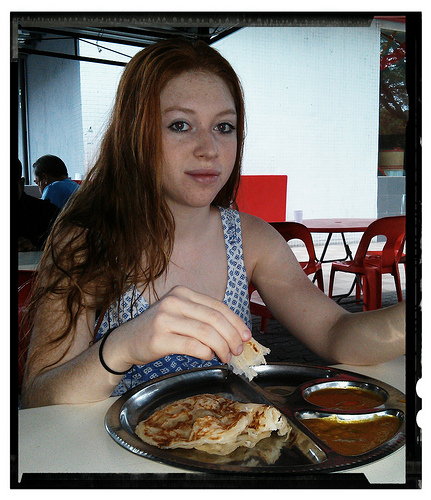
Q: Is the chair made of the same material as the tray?
A: No, the chair is made of plastic and the tray is made of metal.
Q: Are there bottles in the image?
A: No, there are no bottles.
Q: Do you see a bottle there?
A: No, there are no bottles.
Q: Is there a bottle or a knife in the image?
A: No, there are no bottles or knives.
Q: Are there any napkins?
A: No, there are no napkins.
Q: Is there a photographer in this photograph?
A: No, there are no photographers.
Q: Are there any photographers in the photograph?
A: No, there are no photographers.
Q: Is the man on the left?
A: Yes, the man is on the left of the image.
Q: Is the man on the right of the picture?
A: No, the man is on the left of the image.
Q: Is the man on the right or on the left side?
A: The man is on the left of the image.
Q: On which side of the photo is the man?
A: The man is on the left of the image.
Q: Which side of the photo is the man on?
A: The man is on the left of the image.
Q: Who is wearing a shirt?
A: The man is wearing a shirt.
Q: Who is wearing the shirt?
A: The man is wearing a shirt.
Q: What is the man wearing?
A: The man is wearing a shirt.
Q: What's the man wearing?
A: The man is wearing a shirt.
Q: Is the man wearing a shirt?
A: Yes, the man is wearing a shirt.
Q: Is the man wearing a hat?
A: No, the man is wearing a shirt.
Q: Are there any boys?
A: No, there are no boys.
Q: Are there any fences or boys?
A: No, there are no boys or fences.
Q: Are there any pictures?
A: No, there are no pictures.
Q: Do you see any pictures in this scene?
A: No, there are no pictures.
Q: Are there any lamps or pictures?
A: No, there are no pictures or lamps.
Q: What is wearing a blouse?
A: The wall is wearing a blouse.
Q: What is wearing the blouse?
A: The wall is wearing a blouse.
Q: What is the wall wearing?
A: The wall is wearing a blouse.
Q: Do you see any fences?
A: No, there are no fences.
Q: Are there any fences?
A: No, there are no fences.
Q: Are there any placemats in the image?
A: No, there are no placemats.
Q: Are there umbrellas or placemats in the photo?
A: No, there are no placemats or umbrellas.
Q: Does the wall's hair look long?
A: Yes, the hair is long.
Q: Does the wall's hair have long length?
A: Yes, the hair is long.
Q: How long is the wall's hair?
A: The hair is long.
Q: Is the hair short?
A: No, the hair is long.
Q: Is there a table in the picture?
A: Yes, there is a table.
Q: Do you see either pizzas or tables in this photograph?
A: Yes, there is a table.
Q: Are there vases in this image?
A: No, there are no vases.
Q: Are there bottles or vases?
A: No, there are no vases or bottles.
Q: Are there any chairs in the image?
A: Yes, there is a chair.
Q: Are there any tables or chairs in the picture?
A: Yes, there is a chair.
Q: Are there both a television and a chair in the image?
A: No, there is a chair but no televisions.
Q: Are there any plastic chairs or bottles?
A: Yes, there is a plastic chair.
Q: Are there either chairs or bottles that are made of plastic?
A: Yes, the chair is made of plastic.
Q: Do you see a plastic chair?
A: Yes, there is a chair that is made of plastic.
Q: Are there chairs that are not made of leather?
A: Yes, there is a chair that is made of plastic.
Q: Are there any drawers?
A: No, there are no drawers.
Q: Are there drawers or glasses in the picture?
A: No, there are no drawers or glasses.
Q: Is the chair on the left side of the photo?
A: No, the chair is on the right of the image.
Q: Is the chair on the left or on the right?
A: The chair is on the right of the image.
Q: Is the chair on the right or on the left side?
A: The chair is on the right of the image.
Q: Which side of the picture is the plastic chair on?
A: The chair is on the right of the image.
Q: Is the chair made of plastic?
A: Yes, the chair is made of plastic.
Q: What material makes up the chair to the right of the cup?
A: The chair is made of plastic.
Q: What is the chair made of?
A: The chair is made of plastic.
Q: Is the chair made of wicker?
A: No, the chair is made of plastic.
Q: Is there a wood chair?
A: No, there is a chair but it is made of plastic.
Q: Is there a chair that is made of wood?
A: No, there is a chair but it is made of plastic.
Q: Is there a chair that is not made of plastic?
A: No, there is a chair but it is made of plastic.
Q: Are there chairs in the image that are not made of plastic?
A: No, there is a chair but it is made of plastic.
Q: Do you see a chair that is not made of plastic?
A: No, there is a chair but it is made of plastic.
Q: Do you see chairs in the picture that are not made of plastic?
A: No, there is a chair but it is made of plastic.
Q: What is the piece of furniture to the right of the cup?
A: The piece of furniture is a chair.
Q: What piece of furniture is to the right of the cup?
A: The piece of furniture is a chair.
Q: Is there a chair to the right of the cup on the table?
A: Yes, there is a chair to the right of the cup.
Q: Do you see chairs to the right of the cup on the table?
A: Yes, there is a chair to the right of the cup.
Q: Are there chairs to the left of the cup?
A: No, the chair is to the right of the cup.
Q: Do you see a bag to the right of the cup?
A: No, there is a chair to the right of the cup.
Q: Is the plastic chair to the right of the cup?
A: Yes, the chair is to the right of the cup.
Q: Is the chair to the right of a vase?
A: No, the chair is to the right of the cup.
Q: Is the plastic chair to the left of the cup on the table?
A: No, the chair is to the right of the cup.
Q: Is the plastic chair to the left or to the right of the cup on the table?
A: The chair is to the right of the cup.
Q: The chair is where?
A: The chair is at the table.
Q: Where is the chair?
A: The chair is at the table.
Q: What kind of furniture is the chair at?
A: The chair is at the table.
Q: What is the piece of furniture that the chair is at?
A: The piece of furniture is a table.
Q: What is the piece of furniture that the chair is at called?
A: The piece of furniture is a table.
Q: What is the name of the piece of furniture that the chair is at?
A: The piece of furniture is a table.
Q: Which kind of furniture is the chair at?
A: The chair is at the table.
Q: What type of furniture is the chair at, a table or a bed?
A: The chair is at a table.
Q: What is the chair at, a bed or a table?
A: The chair is at a table.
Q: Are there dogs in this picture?
A: No, there are no dogs.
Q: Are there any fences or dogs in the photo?
A: No, there are no dogs or fences.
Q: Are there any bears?
A: No, there are no bears.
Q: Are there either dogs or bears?
A: No, there are no bears or dogs.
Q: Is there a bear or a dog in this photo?
A: No, there are no bears or dogs.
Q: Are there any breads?
A: Yes, there is a bread.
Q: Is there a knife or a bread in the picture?
A: Yes, there is a bread.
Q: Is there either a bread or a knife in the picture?
A: Yes, there is a bread.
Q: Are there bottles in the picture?
A: No, there are no bottles.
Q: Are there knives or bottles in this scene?
A: No, there are no bottles or knives.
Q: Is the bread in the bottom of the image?
A: Yes, the bread is in the bottom of the image.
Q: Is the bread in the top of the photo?
A: No, the bread is in the bottom of the image.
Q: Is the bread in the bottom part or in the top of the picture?
A: The bread is in the bottom of the image.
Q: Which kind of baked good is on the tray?
A: The food is a bread.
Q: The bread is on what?
A: The bread is on the tray.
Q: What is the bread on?
A: The bread is on the tray.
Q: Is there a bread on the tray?
A: Yes, there is a bread on the tray.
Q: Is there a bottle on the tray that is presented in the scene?
A: No, there is a bread on the tray.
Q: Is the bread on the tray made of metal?
A: Yes, the bread is on the tray.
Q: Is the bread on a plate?
A: No, the bread is on the tray.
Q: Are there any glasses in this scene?
A: No, there are no glasses.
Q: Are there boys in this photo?
A: No, there are no boys.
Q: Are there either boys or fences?
A: No, there are no boys or fences.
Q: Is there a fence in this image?
A: No, there are no fences.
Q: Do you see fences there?
A: No, there are no fences.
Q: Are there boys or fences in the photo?
A: No, there are no fences or boys.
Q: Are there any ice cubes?
A: No, there are no ice cubes.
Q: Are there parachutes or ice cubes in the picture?
A: No, there are no ice cubes or parachutes.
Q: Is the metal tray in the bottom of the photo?
A: Yes, the tray is in the bottom of the image.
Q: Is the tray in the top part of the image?
A: No, the tray is in the bottom of the image.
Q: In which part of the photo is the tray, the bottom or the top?
A: The tray is in the bottom of the image.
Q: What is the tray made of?
A: The tray is made of metal.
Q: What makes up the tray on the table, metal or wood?
A: The tray is made of metal.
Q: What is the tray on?
A: The tray is on the table.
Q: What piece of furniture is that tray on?
A: The tray is on the table.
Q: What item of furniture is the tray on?
A: The tray is on the table.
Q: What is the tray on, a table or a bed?
A: The tray is on a table.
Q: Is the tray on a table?
A: Yes, the tray is on a table.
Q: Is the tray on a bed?
A: No, the tray is on a table.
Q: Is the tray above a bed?
A: No, the tray is above the table.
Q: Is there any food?
A: Yes, there is food.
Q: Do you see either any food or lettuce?
A: Yes, there is food.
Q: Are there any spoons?
A: No, there are no spoons.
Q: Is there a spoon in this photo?
A: No, there are no spoons.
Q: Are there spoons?
A: No, there are no spoons.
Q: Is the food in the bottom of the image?
A: Yes, the food is in the bottom of the image.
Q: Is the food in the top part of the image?
A: No, the food is in the bottom of the image.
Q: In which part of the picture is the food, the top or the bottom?
A: The food is in the bottom of the image.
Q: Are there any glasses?
A: No, there are no glasses.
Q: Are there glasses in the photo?
A: No, there are no glasses.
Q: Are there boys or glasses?
A: No, there are no glasses or boys.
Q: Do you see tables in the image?
A: Yes, there is a table.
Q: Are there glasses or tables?
A: Yes, there is a table.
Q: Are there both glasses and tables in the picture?
A: No, there is a table but no glasses.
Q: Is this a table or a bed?
A: This is a table.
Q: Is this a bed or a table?
A: This is a table.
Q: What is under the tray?
A: The table is under the tray.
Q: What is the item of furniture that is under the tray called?
A: The piece of furniture is a table.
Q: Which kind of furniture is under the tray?
A: The piece of furniture is a table.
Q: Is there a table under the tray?
A: Yes, there is a table under the tray.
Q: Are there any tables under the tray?
A: Yes, there is a table under the tray.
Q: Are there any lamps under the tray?
A: No, there is a table under the tray.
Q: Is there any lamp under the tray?
A: No, there is a table under the tray.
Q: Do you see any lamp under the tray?
A: No, there is a table under the tray.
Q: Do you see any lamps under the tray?
A: No, there is a table under the tray.